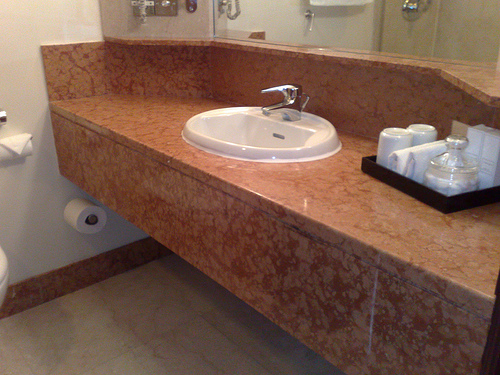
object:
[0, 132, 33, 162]
toilet paper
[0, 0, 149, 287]
wall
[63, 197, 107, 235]
toilet paper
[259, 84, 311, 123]
faucet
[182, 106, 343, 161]
sink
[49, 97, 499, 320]
counter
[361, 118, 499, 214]
amenities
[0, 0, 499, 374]
restroom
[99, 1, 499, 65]
mirror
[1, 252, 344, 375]
floor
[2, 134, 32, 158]
flip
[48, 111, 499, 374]
front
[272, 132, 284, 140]
hole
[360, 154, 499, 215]
tray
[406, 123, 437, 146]
cup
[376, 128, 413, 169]
cup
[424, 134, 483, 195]
jar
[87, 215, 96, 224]
handle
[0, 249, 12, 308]
toilet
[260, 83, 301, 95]
handle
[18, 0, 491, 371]
bathroom